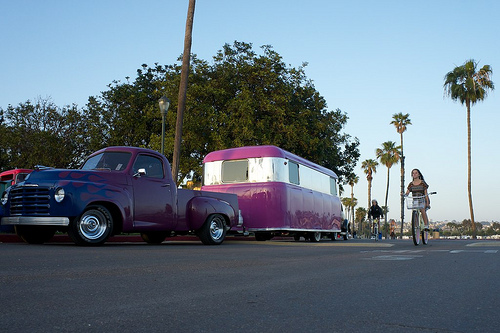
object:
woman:
[400, 168, 430, 228]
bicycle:
[403, 192, 437, 246]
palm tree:
[444, 59, 494, 240]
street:
[0, 238, 500, 333]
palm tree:
[390, 112, 412, 239]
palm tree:
[376, 141, 401, 240]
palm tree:
[361, 159, 379, 239]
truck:
[0, 146, 239, 245]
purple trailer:
[201, 145, 342, 242]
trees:
[0, 40, 361, 238]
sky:
[0, 0, 497, 221]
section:
[204, 157, 340, 198]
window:
[221, 158, 249, 184]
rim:
[68, 205, 115, 247]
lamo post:
[158, 94, 170, 154]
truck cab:
[0, 168, 35, 195]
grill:
[6, 186, 51, 217]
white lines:
[360, 242, 500, 260]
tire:
[199, 214, 226, 245]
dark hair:
[411, 168, 424, 180]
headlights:
[0, 186, 64, 205]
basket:
[406, 199, 426, 209]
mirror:
[132, 168, 146, 177]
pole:
[170, 0, 195, 183]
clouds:
[370, 185, 500, 221]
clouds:
[355, 26, 436, 108]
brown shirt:
[407, 180, 429, 197]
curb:
[10, 235, 250, 244]